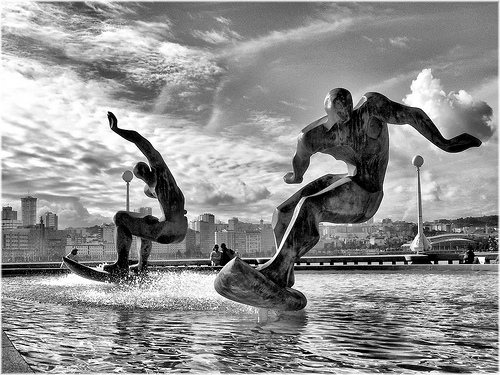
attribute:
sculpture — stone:
[206, 226, 324, 312]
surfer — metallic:
[80, 102, 207, 282]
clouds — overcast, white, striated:
[96, 32, 151, 71]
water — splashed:
[33, 312, 88, 351]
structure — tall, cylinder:
[402, 149, 433, 250]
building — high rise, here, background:
[8, 198, 80, 255]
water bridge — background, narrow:
[355, 247, 414, 262]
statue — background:
[119, 125, 170, 255]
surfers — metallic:
[60, 106, 358, 273]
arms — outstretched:
[123, 125, 174, 196]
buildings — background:
[179, 208, 256, 256]